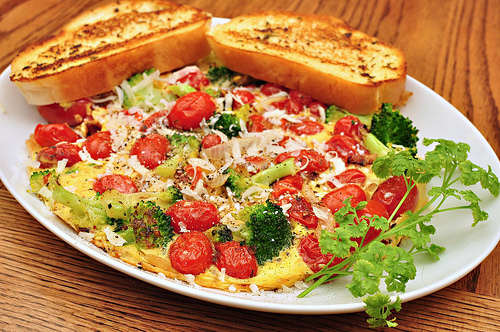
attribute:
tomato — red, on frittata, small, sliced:
[166, 89, 225, 135]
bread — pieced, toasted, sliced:
[225, 17, 397, 98]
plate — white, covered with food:
[412, 114, 483, 136]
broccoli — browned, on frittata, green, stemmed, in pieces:
[369, 112, 419, 153]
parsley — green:
[323, 218, 419, 297]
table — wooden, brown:
[414, 8, 483, 62]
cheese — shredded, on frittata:
[245, 104, 282, 149]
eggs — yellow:
[265, 260, 298, 283]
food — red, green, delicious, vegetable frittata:
[51, 4, 468, 304]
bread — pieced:
[9, 25, 224, 63]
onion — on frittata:
[188, 140, 305, 149]